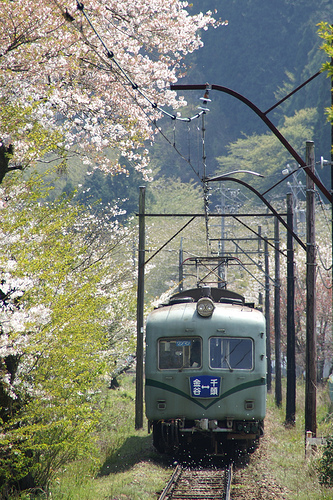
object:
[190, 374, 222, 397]
sign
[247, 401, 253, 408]
light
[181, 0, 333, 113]
ground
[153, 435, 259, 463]
wheels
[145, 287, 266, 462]
car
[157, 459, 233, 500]
tracks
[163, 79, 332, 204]
poles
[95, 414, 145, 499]
grass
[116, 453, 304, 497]
ground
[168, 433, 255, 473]
petals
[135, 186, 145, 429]
poles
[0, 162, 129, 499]
bushes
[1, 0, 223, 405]
cherry blossoms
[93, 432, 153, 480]
shadow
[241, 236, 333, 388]
tree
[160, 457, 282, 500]
gravel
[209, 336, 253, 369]
window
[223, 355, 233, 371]
windshield wiper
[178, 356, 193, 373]
windshield wiper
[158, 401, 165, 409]
head light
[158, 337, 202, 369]
window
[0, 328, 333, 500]
field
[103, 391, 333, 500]
meadow